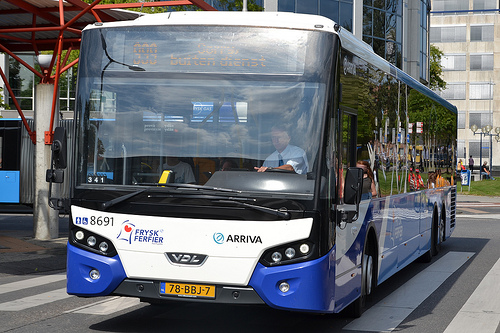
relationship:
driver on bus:
[254, 122, 309, 172] [66, 11, 457, 315]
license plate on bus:
[158, 281, 216, 298] [66, 11, 457, 315]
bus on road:
[66, 11, 457, 315] [2, 294, 500, 331]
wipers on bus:
[102, 182, 292, 219] [66, 11, 457, 315]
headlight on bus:
[89, 269, 100, 279] [66, 11, 457, 315]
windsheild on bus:
[73, 27, 340, 205] [66, 11, 457, 315]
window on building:
[471, 25, 483, 42] [431, 1, 499, 174]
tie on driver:
[277, 153, 284, 166] [254, 122, 309, 172]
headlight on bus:
[280, 281, 288, 291] [66, 11, 457, 315]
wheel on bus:
[358, 230, 375, 317] [66, 11, 457, 315]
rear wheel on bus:
[425, 213, 446, 260] [66, 11, 457, 315]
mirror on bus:
[341, 167, 362, 221] [66, 11, 457, 315]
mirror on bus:
[52, 127, 67, 171] [66, 11, 457, 315]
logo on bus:
[212, 232, 262, 244] [66, 11, 457, 315]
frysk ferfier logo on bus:
[116, 219, 165, 246] [66, 11, 457, 315]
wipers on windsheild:
[102, 182, 292, 219] [73, 27, 340, 205]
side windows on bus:
[338, 47, 457, 199] [66, 11, 457, 315]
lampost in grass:
[470, 123, 493, 180] [455, 173, 499, 198]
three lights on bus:
[71, 225, 115, 253] [66, 11, 457, 315]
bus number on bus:
[90, 216, 114, 227] [66, 11, 457, 315]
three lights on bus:
[264, 241, 315, 264] [66, 11, 457, 315]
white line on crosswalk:
[344, 250, 476, 329] [346, 248, 500, 331]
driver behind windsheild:
[254, 122, 309, 172] [73, 27, 340, 205]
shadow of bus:
[342, 236, 490, 332] [66, 11, 457, 315]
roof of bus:
[86, 11, 461, 75] [66, 11, 457, 315]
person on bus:
[157, 145, 196, 186] [66, 11, 457, 315]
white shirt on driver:
[262, 145, 309, 174] [254, 122, 309, 172]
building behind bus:
[431, 1, 499, 174] [66, 11, 457, 315]